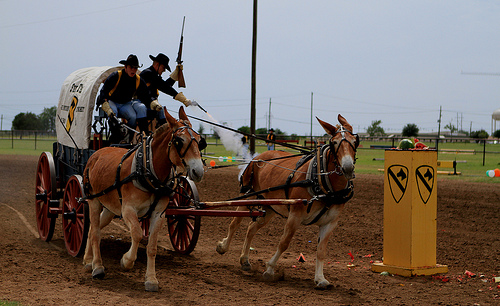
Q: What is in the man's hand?
A: A shotgun.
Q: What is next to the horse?
A: A yellow stand.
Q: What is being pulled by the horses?
A: A wagon.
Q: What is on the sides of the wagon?
A: Wheels.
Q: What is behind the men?
A: A cover for the wagon.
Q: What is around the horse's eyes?
A: Eye shields.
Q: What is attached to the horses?
A: Reigns.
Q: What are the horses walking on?
A: Dirt.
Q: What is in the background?
A: Grass.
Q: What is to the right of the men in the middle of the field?
A: A tall black pole.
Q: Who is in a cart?
A: Two men.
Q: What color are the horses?
A: Brown.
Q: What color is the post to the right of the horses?
A: Yellow.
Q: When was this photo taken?
A: Daytime.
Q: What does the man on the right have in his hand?
A: Gun.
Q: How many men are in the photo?
A: Two.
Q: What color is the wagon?
A: White.